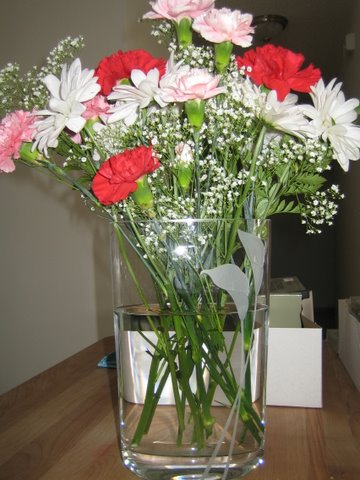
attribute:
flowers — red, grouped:
[92, 44, 322, 206]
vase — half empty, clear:
[110, 218, 272, 479]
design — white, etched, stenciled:
[198, 228, 265, 477]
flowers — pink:
[0, 0, 256, 175]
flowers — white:
[31, 60, 360, 170]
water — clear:
[113, 303, 269, 458]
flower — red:
[93, 145, 160, 206]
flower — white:
[27, 56, 101, 157]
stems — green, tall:
[18, 22, 332, 449]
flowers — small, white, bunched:
[0, 20, 346, 235]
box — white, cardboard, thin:
[120, 310, 324, 406]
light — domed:
[244, 13, 288, 45]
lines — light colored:
[0, 341, 124, 479]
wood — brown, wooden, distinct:
[0, 336, 360, 477]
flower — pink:
[192, 7, 254, 48]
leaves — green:
[255, 162, 325, 218]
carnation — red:
[93, 49, 167, 100]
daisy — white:
[304, 78, 359, 173]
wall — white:
[0, 0, 175, 398]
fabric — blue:
[97, 349, 116, 368]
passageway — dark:
[187, 0, 360, 331]